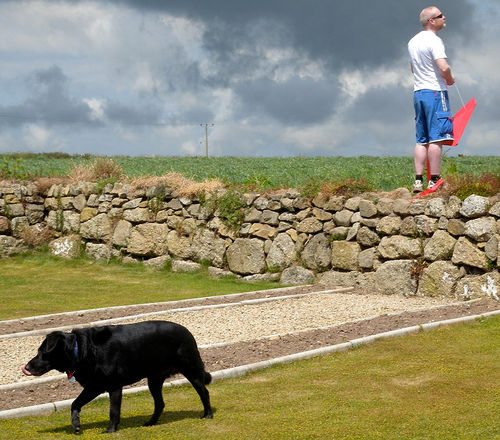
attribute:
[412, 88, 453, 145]
shorts — blue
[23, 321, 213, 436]
lab — black, full grown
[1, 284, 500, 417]
walkway — straight, brown, raised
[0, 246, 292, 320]
grass — cut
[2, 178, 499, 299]
wall — rock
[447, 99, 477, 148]
kite — red, bright red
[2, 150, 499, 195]
field — green, overgrown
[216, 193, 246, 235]
plant — small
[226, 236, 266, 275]
stone — pilled up, irregular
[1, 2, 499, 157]
sky — cloudy, overcast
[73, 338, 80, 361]
collar — blue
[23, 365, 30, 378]
tongue — out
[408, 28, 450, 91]
shirt — white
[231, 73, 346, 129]
cloud — dark